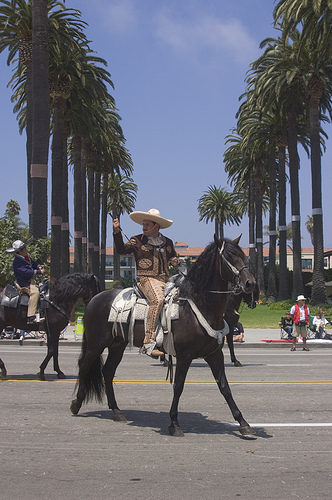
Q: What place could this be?
A: It is a road.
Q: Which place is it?
A: It is a road.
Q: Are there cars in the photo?
A: No, there are no cars.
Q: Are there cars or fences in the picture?
A: No, there are no cars or fences.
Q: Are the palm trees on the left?
A: Yes, the palm trees are on the left of the image.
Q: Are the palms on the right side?
A: No, the palms are on the left of the image.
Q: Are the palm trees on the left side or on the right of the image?
A: The palm trees are on the left of the image.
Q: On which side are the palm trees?
A: The palm trees are on the left of the image.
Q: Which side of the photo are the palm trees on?
A: The palm trees are on the left of the image.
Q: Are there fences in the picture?
A: No, there are no fences.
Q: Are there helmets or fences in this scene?
A: No, there are no fences or helmets.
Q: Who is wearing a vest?
A: The man is wearing a vest.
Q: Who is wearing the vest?
A: The man is wearing a vest.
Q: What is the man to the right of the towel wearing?
A: The man is wearing a vest.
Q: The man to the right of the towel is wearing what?
A: The man is wearing a vest.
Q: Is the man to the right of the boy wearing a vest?
A: Yes, the man is wearing a vest.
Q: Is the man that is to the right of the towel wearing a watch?
A: No, the man is wearing a vest.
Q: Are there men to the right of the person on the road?
A: Yes, there is a man to the right of the person.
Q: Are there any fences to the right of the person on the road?
A: No, there is a man to the right of the person.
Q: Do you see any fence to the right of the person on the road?
A: No, there is a man to the right of the person.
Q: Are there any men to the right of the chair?
A: Yes, there is a man to the right of the chair.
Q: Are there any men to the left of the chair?
A: No, the man is to the right of the chair.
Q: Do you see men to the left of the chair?
A: No, the man is to the right of the chair.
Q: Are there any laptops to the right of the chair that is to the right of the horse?
A: No, there is a man to the right of the chair.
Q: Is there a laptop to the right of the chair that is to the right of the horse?
A: No, there is a man to the right of the chair.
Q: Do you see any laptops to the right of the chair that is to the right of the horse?
A: No, there is a man to the right of the chair.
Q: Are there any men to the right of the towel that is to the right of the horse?
A: Yes, there is a man to the right of the towel.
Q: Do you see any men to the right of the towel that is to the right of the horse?
A: Yes, there is a man to the right of the towel.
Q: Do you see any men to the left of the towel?
A: No, the man is to the right of the towel.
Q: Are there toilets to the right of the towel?
A: No, there is a man to the right of the towel.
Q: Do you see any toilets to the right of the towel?
A: No, there is a man to the right of the towel.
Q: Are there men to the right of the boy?
A: Yes, there is a man to the right of the boy.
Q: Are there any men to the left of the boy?
A: No, the man is to the right of the boy.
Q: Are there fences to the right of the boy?
A: No, there is a man to the right of the boy.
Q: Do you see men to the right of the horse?
A: Yes, there is a man to the right of the horse.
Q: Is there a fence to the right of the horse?
A: No, there is a man to the right of the horse.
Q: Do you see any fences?
A: No, there are no fences.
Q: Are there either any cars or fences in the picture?
A: No, there are no fences or cars.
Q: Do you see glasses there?
A: No, there are no glasses.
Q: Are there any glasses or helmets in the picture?
A: No, there are no glasses or helmets.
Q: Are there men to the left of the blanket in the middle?
A: Yes, there is a man to the left of the blanket.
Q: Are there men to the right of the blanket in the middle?
A: No, the man is to the left of the blanket.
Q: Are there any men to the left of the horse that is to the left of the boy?
A: Yes, there is a man to the left of the horse.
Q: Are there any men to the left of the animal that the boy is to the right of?
A: Yes, there is a man to the left of the horse.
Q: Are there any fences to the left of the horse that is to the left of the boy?
A: No, there is a man to the left of the horse.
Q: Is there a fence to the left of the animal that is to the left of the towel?
A: No, there is a man to the left of the horse.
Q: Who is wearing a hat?
A: The man is wearing a hat.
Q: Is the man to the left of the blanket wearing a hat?
A: Yes, the man is wearing a hat.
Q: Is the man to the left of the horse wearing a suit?
A: No, the man is wearing a hat.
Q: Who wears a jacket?
A: The man wears a jacket.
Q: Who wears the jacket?
A: The man wears a jacket.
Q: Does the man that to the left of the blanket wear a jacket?
A: Yes, the man wears a jacket.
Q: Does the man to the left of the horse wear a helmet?
A: No, the man wears a jacket.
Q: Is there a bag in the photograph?
A: No, there are no bags.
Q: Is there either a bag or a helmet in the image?
A: No, there are no bags or helmets.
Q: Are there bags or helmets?
A: No, there are no bags or helmets.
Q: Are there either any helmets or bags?
A: No, there are no bags or helmets.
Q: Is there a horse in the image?
A: Yes, there is a horse.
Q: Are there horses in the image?
A: Yes, there is a horse.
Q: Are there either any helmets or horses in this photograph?
A: Yes, there is a horse.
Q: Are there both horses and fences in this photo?
A: No, there is a horse but no fences.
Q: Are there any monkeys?
A: No, there are no monkeys.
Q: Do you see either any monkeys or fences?
A: No, there are no monkeys or fences.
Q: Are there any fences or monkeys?
A: No, there are no monkeys or fences.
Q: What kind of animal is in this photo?
A: The animal is a horse.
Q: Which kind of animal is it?
A: The animal is a horse.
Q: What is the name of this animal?
A: This is a horse.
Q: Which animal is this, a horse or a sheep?
A: This is a horse.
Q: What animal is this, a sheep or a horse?
A: This is a horse.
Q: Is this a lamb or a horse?
A: This is a horse.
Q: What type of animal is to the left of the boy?
A: The animal is a horse.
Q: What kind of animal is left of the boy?
A: The animal is a horse.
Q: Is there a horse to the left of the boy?
A: Yes, there is a horse to the left of the boy.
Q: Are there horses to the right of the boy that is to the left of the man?
A: No, the horse is to the left of the boy.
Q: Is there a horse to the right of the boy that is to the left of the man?
A: No, the horse is to the left of the boy.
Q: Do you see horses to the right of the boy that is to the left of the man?
A: No, the horse is to the left of the boy.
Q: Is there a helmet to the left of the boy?
A: No, there is a horse to the left of the boy.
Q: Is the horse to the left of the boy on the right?
A: Yes, the horse is to the left of the boy.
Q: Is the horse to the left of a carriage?
A: No, the horse is to the left of the boy.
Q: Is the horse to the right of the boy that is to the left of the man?
A: No, the horse is to the left of the boy.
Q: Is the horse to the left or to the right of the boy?
A: The horse is to the left of the boy.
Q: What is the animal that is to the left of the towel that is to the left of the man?
A: The animal is a horse.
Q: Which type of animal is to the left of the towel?
A: The animal is a horse.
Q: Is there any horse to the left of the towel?
A: Yes, there is a horse to the left of the towel.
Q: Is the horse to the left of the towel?
A: Yes, the horse is to the left of the towel.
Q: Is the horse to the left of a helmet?
A: No, the horse is to the left of the towel.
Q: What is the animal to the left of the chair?
A: The animal is a horse.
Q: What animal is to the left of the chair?
A: The animal is a horse.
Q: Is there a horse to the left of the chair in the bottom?
A: Yes, there is a horse to the left of the chair.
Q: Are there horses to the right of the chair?
A: No, the horse is to the left of the chair.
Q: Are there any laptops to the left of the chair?
A: No, there is a horse to the left of the chair.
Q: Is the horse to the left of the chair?
A: Yes, the horse is to the left of the chair.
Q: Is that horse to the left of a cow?
A: No, the horse is to the left of the chair.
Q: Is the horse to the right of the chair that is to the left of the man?
A: No, the horse is to the left of the chair.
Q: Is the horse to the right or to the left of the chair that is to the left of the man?
A: The horse is to the left of the chair.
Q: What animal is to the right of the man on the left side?
A: The animal is a horse.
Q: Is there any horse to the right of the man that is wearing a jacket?
A: Yes, there is a horse to the right of the man.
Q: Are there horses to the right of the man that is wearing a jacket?
A: Yes, there is a horse to the right of the man.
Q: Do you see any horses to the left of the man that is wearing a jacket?
A: No, the horse is to the right of the man.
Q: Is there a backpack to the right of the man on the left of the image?
A: No, there is a horse to the right of the man.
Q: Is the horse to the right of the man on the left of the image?
A: Yes, the horse is to the right of the man.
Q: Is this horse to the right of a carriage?
A: No, the horse is to the right of the man.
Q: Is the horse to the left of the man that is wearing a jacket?
A: No, the horse is to the right of the man.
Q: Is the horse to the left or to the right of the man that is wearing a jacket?
A: The horse is to the right of the man.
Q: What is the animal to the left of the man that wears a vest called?
A: The animal is a horse.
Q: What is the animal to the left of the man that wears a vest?
A: The animal is a horse.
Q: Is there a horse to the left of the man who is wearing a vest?
A: Yes, there is a horse to the left of the man.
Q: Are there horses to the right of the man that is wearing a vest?
A: No, the horse is to the left of the man.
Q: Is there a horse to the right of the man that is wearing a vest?
A: No, the horse is to the left of the man.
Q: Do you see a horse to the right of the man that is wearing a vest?
A: No, the horse is to the left of the man.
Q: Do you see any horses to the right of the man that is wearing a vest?
A: No, the horse is to the left of the man.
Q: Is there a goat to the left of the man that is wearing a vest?
A: No, there is a horse to the left of the man.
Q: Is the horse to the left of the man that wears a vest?
A: Yes, the horse is to the left of the man.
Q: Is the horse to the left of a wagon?
A: No, the horse is to the left of the man.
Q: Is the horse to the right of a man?
A: No, the horse is to the left of a man.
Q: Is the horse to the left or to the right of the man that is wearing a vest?
A: The horse is to the left of the man.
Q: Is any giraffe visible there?
A: No, there are no giraffes.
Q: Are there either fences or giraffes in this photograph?
A: No, there are no giraffes or fences.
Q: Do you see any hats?
A: Yes, there is a hat.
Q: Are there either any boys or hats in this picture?
A: Yes, there is a hat.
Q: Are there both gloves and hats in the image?
A: No, there is a hat but no gloves.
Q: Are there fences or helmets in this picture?
A: No, there are no fences or helmets.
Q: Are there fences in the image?
A: No, there are no fences.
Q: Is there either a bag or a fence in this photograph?
A: No, there are no fences or bags.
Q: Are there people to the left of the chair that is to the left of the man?
A: Yes, there is a person to the left of the chair.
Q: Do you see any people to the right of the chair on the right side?
A: No, the person is to the left of the chair.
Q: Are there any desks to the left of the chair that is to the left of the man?
A: No, there is a person to the left of the chair.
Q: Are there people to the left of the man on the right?
A: Yes, there is a person to the left of the man.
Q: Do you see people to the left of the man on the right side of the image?
A: Yes, there is a person to the left of the man.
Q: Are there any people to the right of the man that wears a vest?
A: No, the person is to the left of the man.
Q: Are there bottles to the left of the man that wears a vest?
A: No, there is a person to the left of the man.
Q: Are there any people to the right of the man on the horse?
A: Yes, there is a person to the right of the man.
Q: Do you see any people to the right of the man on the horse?
A: Yes, there is a person to the right of the man.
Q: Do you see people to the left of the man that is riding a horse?
A: No, the person is to the right of the man.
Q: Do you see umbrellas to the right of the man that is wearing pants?
A: No, there is a person to the right of the man.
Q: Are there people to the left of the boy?
A: Yes, there is a person to the left of the boy.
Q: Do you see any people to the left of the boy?
A: Yes, there is a person to the left of the boy.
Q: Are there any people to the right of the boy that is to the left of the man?
A: No, the person is to the left of the boy.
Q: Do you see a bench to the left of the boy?
A: No, there is a person to the left of the boy.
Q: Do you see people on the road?
A: Yes, there is a person on the road.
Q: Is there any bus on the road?
A: No, there is a person on the road.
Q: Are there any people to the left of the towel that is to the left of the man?
A: Yes, there is a person to the left of the towel.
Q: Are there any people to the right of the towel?
A: No, the person is to the left of the towel.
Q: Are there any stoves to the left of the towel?
A: No, there is a person to the left of the towel.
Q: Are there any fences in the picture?
A: No, there are no fences.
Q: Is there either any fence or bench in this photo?
A: No, there are no fences or benches.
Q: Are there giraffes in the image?
A: No, there are no giraffes.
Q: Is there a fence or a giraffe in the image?
A: No, there are no giraffes or fences.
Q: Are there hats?
A: Yes, there is a hat.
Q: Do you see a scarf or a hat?
A: Yes, there is a hat.